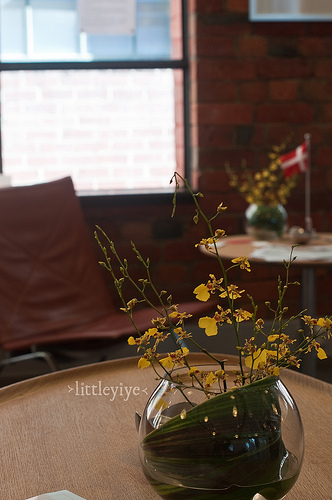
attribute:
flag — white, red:
[278, 137, 309, 178]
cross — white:
[285, 146, 312, 175]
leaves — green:
[188, 269, 244, 311]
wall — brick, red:
[82, 20, 328, 321]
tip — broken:
[163, 172, 186, 219]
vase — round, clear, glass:
[133, 358, 313, 495]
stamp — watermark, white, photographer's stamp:
[62, 375, 151, 406]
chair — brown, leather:
[0, 175, 225, 363]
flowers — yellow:
[126, 275, 316, 392]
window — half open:
[0, 2, 184, 189]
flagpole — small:
[299, 134, 321, 245]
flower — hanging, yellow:
[169, 322, 194, 344]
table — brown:
[3, 348, 331, 500]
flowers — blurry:
[238, 159, 299, 205]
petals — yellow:
[197, 311, 218, 339]